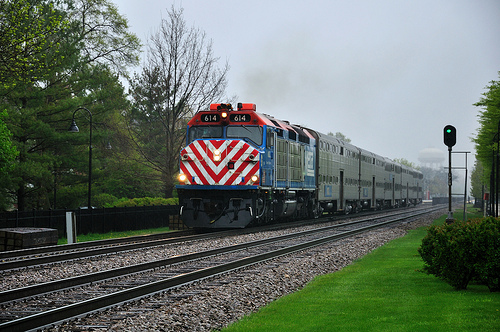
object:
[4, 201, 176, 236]
fence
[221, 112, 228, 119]
light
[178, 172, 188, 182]
light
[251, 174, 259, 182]
light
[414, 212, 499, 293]
bush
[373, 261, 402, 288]
grass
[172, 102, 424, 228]
train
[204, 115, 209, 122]
numbers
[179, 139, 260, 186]
chevron pattern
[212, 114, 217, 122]
number 4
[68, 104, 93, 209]
street light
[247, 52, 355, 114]
smoke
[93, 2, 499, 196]
sky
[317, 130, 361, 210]
train car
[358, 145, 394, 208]
train car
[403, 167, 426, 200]
train car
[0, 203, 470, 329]
rocks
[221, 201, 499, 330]
green space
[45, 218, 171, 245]
green space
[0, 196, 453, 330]
track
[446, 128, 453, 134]
light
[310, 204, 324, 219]
wheel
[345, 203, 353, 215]
wheel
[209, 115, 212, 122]
number 1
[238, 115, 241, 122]
number 1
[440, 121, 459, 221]
pole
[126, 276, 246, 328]
rocks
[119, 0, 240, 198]
tree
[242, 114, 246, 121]
numbers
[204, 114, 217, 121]
numbers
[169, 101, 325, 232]
engine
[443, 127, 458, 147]
traffic light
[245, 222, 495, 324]
space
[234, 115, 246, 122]
number